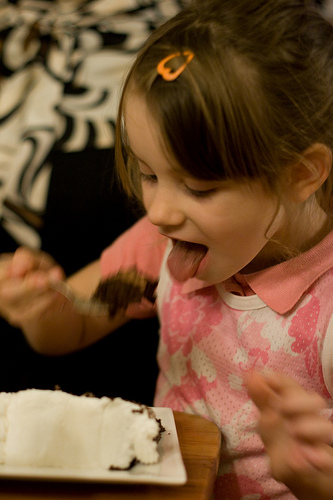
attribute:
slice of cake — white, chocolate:
[4, 398, 149, 473]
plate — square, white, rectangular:
[0, 404, 186, 486]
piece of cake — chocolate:
[100, 266, 161, 317]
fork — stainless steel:
[2, 196, 116, 328]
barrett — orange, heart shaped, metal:
[150, 46, 193, 88]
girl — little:
[17, 7, 326, 457]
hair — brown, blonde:
[143, 3, 333, 150]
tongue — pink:
[163, 239, 210, 284]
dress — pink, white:
[91, 221, 332, 487]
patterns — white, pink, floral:
[173, 318, 236, 405]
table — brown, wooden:
[1, 390, 222, 500]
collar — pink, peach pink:
[239, 258, 331, 317]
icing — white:
[26, 415, 81, 453]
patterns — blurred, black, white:
[19, 10, 101, 113]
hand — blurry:
[0, 248, 74, 330]